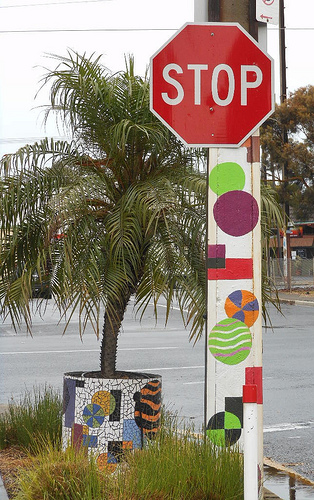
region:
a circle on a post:
[213, 187, 265, 242]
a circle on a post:
[202, 404, 240, 453]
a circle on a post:
[198, 312, 254, 371]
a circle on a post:
[218, 289, 263, 331]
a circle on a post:
[96, 451, 121, 475]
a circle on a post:
[82, 403, 101, 430]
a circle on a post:
[87, 385, 119, 424]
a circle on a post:
[203, 157, 251, 199]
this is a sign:
[146, 18, 275, 146]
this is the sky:
[9, 10, 43, 55]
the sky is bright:
[111, 3, 145, 22]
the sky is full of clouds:
[117, 6, 148, 25]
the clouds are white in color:
[134, 3, 164, 21]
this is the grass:
[137, 431, 193, 492]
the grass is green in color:
[154, 447, 188, 481]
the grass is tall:
[160, 432, 199, 485]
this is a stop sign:
[143, 18, 276, 146]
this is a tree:
[10, 141, 237, 468]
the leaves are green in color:
[108, 217, 148, 282]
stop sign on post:
[145, 18, 285, 152]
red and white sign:
[147, 34, 275, 147]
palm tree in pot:
[18, 195, 188, 497]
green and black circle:
[207, 412, 245, 451]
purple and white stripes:
[202, 314, 256, 368]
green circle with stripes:
[204, 318, 255, 363]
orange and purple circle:
[217, 284, 263, 326]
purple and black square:
[206, 240, 227, 270]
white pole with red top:
[234, 381, 277, 497]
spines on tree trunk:
[92, 297, 122, 384]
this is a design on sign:
[79, 405, 107, 431]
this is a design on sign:
[86, 384, 115, 415]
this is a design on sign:
[88, 449, 124, 483]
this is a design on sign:
[204, 411, 243, 446]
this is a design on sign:
[206, 317, 252, 364]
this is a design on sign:
[223, 289, 260, 331]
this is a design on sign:
[209, 239, 256, 284]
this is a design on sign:
[213, 191, 260, 236]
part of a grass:
[149, 455, 175, 489]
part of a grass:
[136, 453, 152, 476]